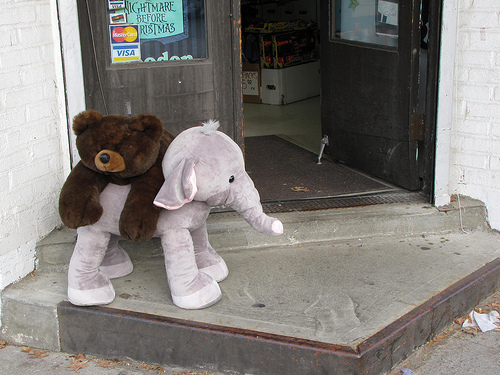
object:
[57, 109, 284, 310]
animals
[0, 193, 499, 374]
steps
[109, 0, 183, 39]
advertisement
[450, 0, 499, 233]
wall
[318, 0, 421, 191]
door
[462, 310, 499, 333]
trash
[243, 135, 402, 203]
mat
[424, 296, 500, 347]
leaves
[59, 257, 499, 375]
edge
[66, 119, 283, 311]
elephant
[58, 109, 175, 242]
bear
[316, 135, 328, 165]
door stop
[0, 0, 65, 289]
brick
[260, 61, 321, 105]
box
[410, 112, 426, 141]
hinge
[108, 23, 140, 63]
logos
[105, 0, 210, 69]
window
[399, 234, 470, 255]
stains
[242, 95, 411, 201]
floor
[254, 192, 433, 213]
jamb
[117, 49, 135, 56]
sign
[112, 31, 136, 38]
sign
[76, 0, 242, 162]
door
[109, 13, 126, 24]
sign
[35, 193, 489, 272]
step